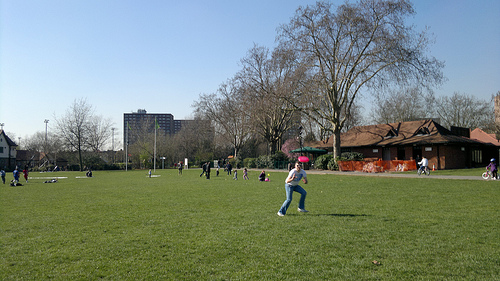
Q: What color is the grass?
A: Green.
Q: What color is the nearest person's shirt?
A: White.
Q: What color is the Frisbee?
A: Pink.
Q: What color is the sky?
A: Blue.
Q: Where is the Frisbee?
A: In the air.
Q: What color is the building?
A: Brown.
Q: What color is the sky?
A: Blue.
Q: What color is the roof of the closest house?
A: Brown.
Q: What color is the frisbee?
A: Pink.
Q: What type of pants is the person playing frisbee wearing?
A: Jeans.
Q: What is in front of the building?
A: Sidewalk.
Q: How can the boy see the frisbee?
A: It is bright red.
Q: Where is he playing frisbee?
A: In a park.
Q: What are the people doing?
A: Enjoying the park.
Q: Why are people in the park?
A: Enjoying a sunny day.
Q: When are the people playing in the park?
A: In the middle of the day.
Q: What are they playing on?
A: The grass.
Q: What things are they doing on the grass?
A: Walking.